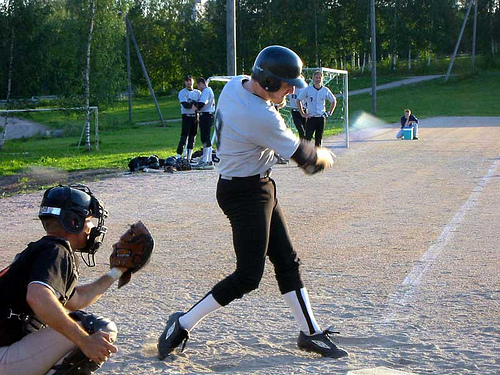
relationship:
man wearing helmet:
[153, 37, 371, 373] [238, 39, 308, 90]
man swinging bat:
[153, 37, 371, 373] [298, 109, 375, 176]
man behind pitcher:
[396, 109, 424, 140] [403, 126, 414, 141]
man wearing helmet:
[6, 179, 154, 368] [42, 179, 107, 250]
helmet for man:
[42, 179, 107, 250] [6, 179, 154, 368]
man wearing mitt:
[6, 179, 154, 368] [108, 221, 153, 277]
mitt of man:
[108, 221, 153, 277] [6, 179, 154, 368]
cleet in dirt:
[291, 330, 357, 362] [247, 348, 265, 363]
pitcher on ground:
[398, 127, 414, 142] [42, 170, 498, 358]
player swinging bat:
[153, 37, 371, 373] [298, 109, 375, 176]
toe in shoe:
[162, 352, 168, 356] [159, 307, 186, 361]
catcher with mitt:
[6, 179, 154, 368] [108, 221, 153, 277]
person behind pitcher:
[401, 125, 413, 138] [403, 126, 414, 141]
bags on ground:
[129, 151, 189, 176] [42, 170, 498, 358]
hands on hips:
[303, 110, 334, 119] [309, 113, 326, 118]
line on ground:
[405, 163, 498, 302] [42, 170, 498, 358]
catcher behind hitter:
[6, 179, 154, 368] [153, 37, 371, 373]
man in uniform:
[175, 74, 202, 164] [179, 90, 192, 158]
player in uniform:
[187, 77, 219, 166] [198, 88, 216, 159]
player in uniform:
[153, 37, 371, 373] [209, 91, 328, 326]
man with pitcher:
[396, 109, 424, 140] [403, 126, 414, 141]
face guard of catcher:
[87, 192, 107, 262] [6, 179, 154, 368]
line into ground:
[405, 163, 498, 302] [42, 170, 498, 358]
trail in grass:
[383, 71, 450, 97] [377, 80, 499, 105]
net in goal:
[330, 120, 342, 139] [307, 66, 355, 147]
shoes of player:
[156, 318, 342, 366] [153, 37, 371, 373]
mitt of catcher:
[108, 221, 153, 277] [6, 179, 154, 368]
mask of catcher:
[87, 192, 107, 262] [6, 179, 154, 368]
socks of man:
[176, 150, 190, 158] [175, 74, 202, 164]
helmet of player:
[238, 39, 308, 90] [153, 37, 371, 373]